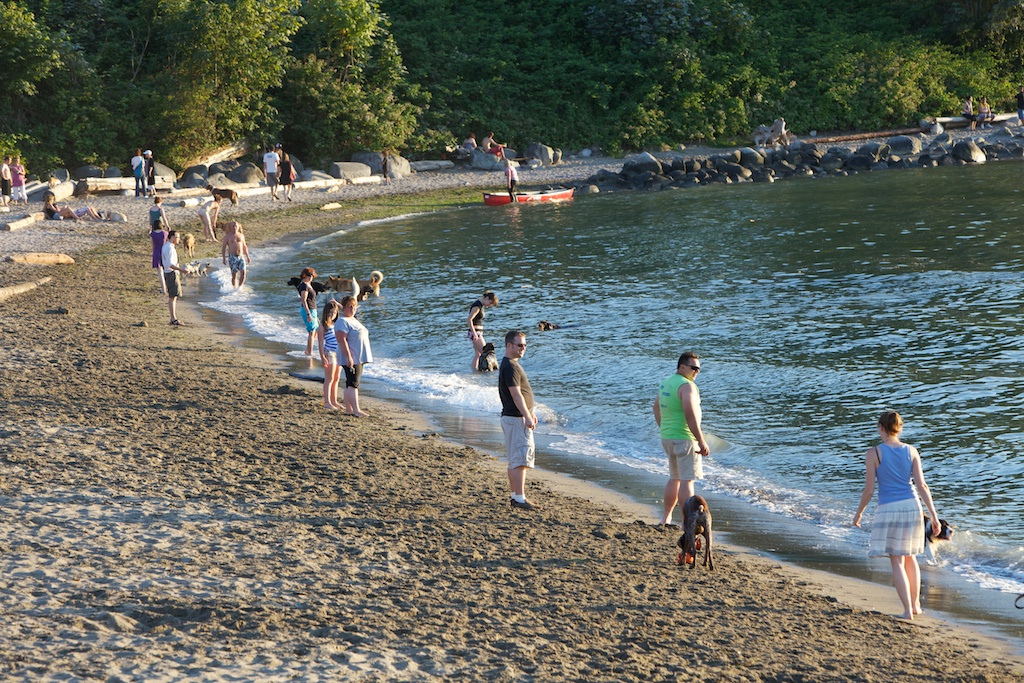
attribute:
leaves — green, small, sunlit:
[214, 1, 301, 108]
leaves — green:
[644, 39, 707, 96]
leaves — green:
[752, 7, 835, 103]